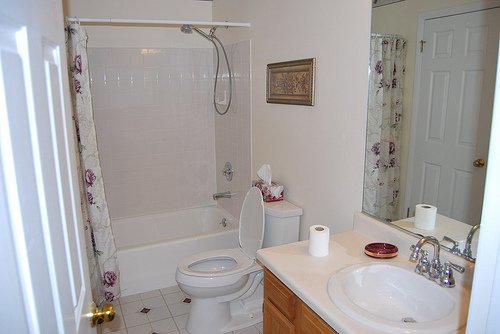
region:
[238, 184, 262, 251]
toilet seat left open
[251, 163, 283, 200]
decorative box of tissue paper on commode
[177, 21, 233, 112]
long shower head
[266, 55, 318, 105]
home decor hanging on wall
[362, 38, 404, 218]
reflection of flower print shower curtain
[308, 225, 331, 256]
toilet paper is not on a holder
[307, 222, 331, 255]
sits comfortably on side of the sink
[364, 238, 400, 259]
soap dish beside faucet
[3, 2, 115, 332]
door is left open to bathroom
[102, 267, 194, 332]
decorative bathroom floor tile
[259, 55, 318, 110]
Gold framed picture of flowers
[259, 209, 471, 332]
Roll of toliet paper sitting by sink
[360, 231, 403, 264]
Red and gold soap dish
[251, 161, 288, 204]
White and red tissue box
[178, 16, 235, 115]
Silver shower head and hose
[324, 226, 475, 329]
Silver faucets on sink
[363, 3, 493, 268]
Mirror reflecting the room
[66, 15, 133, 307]
White flower curtain with purple roses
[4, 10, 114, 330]
Gold handle on white door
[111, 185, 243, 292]
White bath tub with silver faucet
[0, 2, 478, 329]
clean home restroom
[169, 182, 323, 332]
ceramic white toilet bowl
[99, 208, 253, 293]
ceramic white huge tub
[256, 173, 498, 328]
white sink and wooden cupboard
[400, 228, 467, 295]
silver metal sink faucet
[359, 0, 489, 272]
rectangular mirror on wall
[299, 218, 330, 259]
toilet paper roll near sink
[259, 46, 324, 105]
brown rectangular decor frame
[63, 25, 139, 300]
patterned white shower curtain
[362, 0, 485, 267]
reflection in rectangular mirror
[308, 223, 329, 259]
have a round roll of white toilet paper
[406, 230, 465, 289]
single silver bathroom faucet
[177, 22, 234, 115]
silver shower head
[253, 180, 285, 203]
red and purple floral tissue box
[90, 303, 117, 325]
gold metal door knob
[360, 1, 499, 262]
large mirror reflecting bathroom door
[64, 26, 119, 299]
piece of white and purple floral shower curtain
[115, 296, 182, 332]
small section of white and grey linoleum floor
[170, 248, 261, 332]
white porcelain toilet bowl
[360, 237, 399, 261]
red soap dish with yellow stripe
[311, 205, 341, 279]
Toilet paper on vanity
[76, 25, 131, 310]
purple flower shower curtain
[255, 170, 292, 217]
tissue box on back of toilet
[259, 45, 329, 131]
flower picture above toilet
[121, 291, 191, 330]
tile floor with diamonds in the center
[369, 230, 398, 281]
small dish sitting on vanity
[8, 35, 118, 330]
six panel bathroom door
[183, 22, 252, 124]
hand held shower wand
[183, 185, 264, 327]
toilet with the seat up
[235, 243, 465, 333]
bathroom vanity with drawers and cabinet